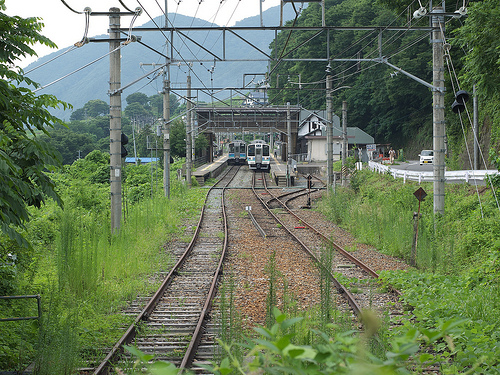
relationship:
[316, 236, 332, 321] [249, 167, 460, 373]
weeds to left of train track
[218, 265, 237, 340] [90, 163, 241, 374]
weeds to right of train track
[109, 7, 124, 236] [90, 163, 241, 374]
pole next to train track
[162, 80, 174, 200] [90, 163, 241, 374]
pole next to train track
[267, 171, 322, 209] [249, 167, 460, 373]
side track to right of train track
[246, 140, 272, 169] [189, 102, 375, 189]
train in train station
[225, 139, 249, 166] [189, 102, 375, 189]
train in train station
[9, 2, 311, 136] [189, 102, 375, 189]
mountains behind train station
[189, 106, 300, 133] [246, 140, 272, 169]
cover over train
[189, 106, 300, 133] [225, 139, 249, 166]
cover over train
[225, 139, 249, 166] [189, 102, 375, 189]
train at train station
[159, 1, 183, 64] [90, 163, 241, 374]
wire over train track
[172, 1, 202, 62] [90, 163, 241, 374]
wire over train track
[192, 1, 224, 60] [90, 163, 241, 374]
wire over train track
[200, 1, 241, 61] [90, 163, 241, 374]
wire over train track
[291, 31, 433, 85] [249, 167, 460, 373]
wire over train track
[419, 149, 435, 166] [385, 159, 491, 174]
car on street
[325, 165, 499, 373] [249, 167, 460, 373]
weeds next to train track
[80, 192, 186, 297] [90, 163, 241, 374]
grass next to train track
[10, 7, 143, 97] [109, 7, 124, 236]
wire attached to pole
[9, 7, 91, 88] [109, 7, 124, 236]
wire attached to pole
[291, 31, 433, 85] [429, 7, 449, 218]
wire attached to pole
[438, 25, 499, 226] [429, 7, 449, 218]
wire attached to pole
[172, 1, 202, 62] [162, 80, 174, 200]
wire attached to pole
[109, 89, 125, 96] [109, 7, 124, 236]
bracket around pole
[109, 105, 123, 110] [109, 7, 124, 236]
bracket around pole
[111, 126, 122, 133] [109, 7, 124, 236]
bracket around pole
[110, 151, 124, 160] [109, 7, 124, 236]
bracket around pole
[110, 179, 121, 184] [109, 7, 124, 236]
bracket around pole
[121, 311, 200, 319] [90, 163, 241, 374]
tie under train track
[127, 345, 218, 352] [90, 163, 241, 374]
tie under train track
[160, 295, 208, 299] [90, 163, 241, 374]
tie under train track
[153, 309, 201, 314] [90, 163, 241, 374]
tie under train track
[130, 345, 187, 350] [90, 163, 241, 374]
tie under train track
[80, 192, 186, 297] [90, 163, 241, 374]
grass by train track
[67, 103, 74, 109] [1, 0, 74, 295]
leaf on tree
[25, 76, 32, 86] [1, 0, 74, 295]
leaf on tree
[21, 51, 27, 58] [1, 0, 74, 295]
leaf on tree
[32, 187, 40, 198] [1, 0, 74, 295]
leaf on tree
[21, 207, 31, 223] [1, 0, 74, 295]
leaf on tree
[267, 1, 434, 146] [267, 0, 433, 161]
trees on mountainside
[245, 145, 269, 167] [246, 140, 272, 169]
front of train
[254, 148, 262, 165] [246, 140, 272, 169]
door on train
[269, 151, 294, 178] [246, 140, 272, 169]
platform next to train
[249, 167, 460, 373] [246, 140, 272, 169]
train track under train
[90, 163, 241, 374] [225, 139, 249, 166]
train track under train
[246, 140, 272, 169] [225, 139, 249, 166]
train next to train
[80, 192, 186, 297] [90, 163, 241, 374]
grass beside train track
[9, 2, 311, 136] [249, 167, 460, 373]
mountains behind train track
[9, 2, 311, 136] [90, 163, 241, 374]
mountains behind train track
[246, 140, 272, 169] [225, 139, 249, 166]
train passing train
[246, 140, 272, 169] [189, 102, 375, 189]
train by train station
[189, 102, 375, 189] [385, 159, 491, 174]
train station next to street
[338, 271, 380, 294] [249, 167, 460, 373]
weeds growing through train track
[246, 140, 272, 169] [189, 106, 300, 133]
train under cover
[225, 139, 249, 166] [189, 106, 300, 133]
train under cover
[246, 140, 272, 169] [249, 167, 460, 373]
train on train track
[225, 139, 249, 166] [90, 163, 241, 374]
train on train track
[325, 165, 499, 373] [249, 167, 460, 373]
weeds to right of train track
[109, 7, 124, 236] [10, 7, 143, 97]
pole holding wire